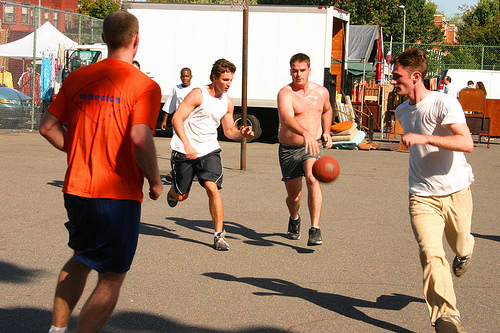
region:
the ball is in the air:
[296, 153, 353, 194]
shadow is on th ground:
[217, 252, 394, 322]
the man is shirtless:
[276, 84, 365, 272]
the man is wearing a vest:
[181, 80, 240, 252]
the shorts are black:
[172, 152, 234, 197]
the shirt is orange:
[68, 63, 157, 197]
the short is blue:
[65, 188, 150, 257]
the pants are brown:
[411, 199, 493, 302]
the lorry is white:
[162, 7, 334, 110]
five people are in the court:
[60, 22, 479, 328]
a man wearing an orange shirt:
[39, 8, 159, 329]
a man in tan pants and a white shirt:
[390, 50, 474, 324]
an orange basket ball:
[313, 152, 339, 184]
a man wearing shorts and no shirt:
[278, 52, 333, 244]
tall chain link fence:
[3, 5, 110, 129]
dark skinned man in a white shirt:
[159, 65, 198, 133]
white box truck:
[53, 3, 349, 143]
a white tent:
[3, 19, 80, 97]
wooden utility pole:
[241, 2, 247, 171]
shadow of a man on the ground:
[198, 270, 428, 330]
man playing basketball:
[55, 11, 475, 331]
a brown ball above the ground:
[313, 153, 340, 184]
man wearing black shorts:
[171, 150, 225, 196]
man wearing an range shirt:
[47, 62, 159, 199]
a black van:
[126, 4, 348, 134]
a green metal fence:
[383, 40, 498, 72]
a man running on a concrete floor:
[388, 44, 475, 331]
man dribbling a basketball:
[278, 55, 340, 248]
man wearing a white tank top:
[171, 85, 230, 155]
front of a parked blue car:
[2, 83, 35, 128]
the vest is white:
[184, 87, 238, 163]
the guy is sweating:
[273, 60, 338, 240]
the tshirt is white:
[391, 102, 483, 184]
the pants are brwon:
[408, 198, 478, 310]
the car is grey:
[6, 85, 45, 132]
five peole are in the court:
[91, 25, 483, 330]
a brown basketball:
[311, 151, 341, 185]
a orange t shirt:
[46, 58, 160, 200]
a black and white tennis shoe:
[304, 227, 324, 247]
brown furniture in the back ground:
[461, 85, 498, 150]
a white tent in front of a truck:
[4, 21, 86, 71]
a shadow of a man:
[202, 265, 442, 332]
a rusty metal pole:
[235, 4, 252, 167]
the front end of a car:
[4, 77, 32, 127]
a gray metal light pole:
[396, 4, 411, 42]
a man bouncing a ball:
[274, 56, 340, 253]